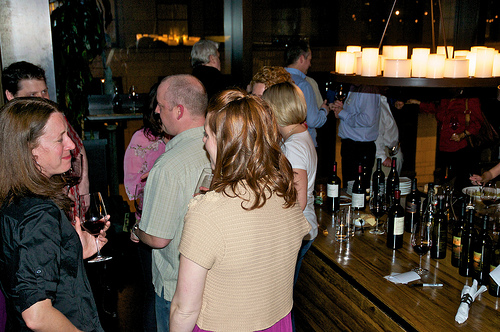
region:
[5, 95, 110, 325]
lady with black shirt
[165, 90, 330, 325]
lady with tan colored shirt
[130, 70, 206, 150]
men with bald spot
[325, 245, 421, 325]
tan wooden counter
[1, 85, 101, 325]
lady with brown hair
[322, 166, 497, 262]
wine bottles on the counter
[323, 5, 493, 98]
candles hanging from ceiling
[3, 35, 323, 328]
Crowd of people together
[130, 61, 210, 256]
guy with grey hair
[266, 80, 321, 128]
blonde hair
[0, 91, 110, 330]
woman in black shirt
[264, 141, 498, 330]
brown wooden table covered with bottles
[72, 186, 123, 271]
glass of red wine in woman's hand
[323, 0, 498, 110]
circular light hanging over table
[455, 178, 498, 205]
white plate of food on wooden table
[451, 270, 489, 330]
silverware wrapped in white napkin on table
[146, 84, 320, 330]
woman with red hair near wooden table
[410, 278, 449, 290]
white marker with black cap lying on table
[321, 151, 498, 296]
many alcoholic beverage bottles on wooden table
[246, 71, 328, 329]
blonde woman leaning against wooden table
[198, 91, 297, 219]
shiny brown curly hair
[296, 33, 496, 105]
lights hanging from the ceiling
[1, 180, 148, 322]
a black silky shirt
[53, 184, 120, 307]
a wine glass with wine in it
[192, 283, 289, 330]
a purple dress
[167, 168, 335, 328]
a brown sweater on a woman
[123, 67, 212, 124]
a man with very short hair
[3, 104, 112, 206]
a lady with dark brown hair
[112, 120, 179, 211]
a pink shirt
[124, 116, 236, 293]
a man wearing a collared green shirt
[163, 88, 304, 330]
a woman in a stripped shirt in a bar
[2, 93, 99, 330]
a woman in a black shirt in a bar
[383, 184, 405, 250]
a wine bottle on a bar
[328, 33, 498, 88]
a chandelier with candles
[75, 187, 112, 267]
a glass a wine in a woman's hand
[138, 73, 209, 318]
a man in a mint green shirt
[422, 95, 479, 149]
a red shirt on a person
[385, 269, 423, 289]
a napkin sitting on a bar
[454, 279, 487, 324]
a napkin in a napkin ring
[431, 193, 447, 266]
a wine bottle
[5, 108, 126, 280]
Woman holding a glass of wine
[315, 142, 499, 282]
Bar full of bottles and glasses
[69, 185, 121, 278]
Glass of red wine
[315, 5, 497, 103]
Chandelier made from faux candles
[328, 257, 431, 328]
Wood grain bar top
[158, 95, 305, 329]
Woman in pink short sleeved top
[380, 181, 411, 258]
Bottle of red wine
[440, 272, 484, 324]
Rolled up cloth napkin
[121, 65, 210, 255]
Balding man holding a wine glass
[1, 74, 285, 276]
Two women talking to each other